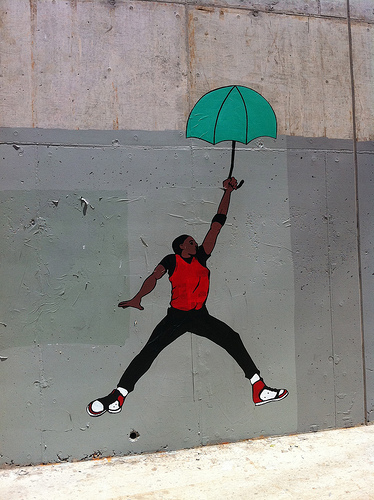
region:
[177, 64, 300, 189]
A green umbrella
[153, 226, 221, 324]
A drawing of a young man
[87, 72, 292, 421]
A guy jumping with an umbrella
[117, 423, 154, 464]
A hole in the wall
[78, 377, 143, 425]
A drawing of a tennis shoe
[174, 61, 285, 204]
A drawing of an umbrella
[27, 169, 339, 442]
a painting of a person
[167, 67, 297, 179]
this is an umbrella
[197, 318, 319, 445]
the leg of a person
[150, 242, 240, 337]
the vest is red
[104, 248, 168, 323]
this is a hand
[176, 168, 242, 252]
this is a hand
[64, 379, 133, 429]
this is a shoe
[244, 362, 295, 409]
this is a shoe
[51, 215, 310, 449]
the person is off the ground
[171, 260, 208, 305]
a red shirt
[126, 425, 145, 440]
a hole on the wall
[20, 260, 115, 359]
the wall is grey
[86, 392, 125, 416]
the drawing is wearing shoes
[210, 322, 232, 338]
the pants are black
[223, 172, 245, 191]
man is holding a umbrella handle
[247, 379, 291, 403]
the shoe is red and white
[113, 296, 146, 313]
the hand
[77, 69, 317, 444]
drawing on the wall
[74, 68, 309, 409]
drawing on the wall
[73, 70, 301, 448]
drawing on the wall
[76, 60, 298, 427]
drawing on the wall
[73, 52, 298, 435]
drawing on the wall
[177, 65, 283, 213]
drawing of green umbrella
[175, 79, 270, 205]
drawing of green umbrella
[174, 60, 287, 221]
drawing of green umbrella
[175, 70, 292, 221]
drawing of green umbrella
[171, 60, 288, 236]
drawing of green umbrella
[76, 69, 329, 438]
a drawing on the wall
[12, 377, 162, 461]
a section of the wall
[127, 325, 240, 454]
a section of the wall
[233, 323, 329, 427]
a section of the wall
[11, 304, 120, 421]
a section of the wall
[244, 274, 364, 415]
a section of the wall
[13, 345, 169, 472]
a section of the wall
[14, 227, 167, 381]
a section of the wall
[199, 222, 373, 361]
a section of the wall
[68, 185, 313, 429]
the picture of a man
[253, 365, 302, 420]
black white and red shoe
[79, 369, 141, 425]
black white and red shoe